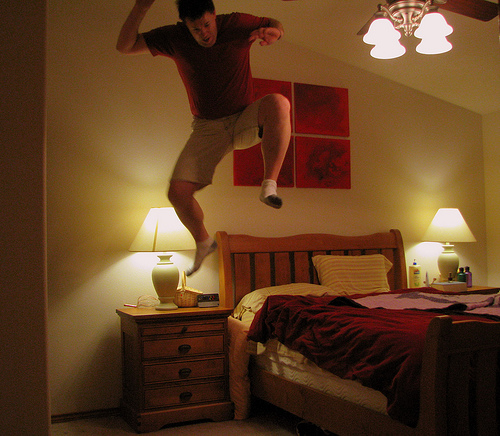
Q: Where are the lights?
A: Ceiling fan.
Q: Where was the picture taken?
A: In a bedroom.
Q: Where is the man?
A: In the air.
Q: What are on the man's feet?
A: White socks.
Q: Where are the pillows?
A: On the bed.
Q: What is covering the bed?
A: A blanket.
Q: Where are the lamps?
A: On the nightstands.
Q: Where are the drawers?
A: In the nightstand.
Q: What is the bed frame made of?
A: Wood.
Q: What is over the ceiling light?
A: A fan.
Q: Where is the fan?
A: On the ceiling.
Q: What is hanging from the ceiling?
A: Light fixture.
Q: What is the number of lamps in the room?
A: 2.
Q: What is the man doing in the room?
A: Jumping.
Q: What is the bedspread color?
A: Red.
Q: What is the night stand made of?
A: Wood.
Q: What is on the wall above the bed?
A: A painting.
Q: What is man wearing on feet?
A: Socks.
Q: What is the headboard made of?
A: Wood.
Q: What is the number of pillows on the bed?
A: 2.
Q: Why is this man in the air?
A: Jumping.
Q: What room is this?
A: Bedroom.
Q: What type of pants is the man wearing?
A: Shorts.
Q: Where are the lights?
A: Side tables and ceiling.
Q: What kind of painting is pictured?
A: Abstract.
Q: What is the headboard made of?
A: Wood.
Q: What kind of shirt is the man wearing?
A: T-shirt.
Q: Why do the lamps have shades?
A: To soften the light.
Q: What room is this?
A: Bedroom.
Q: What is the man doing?
A: Jumping.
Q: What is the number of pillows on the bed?
A: 2.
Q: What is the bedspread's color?
A: Red.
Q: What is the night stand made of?
A: Wood.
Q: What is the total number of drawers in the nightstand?
A: 4.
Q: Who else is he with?
A: No one.